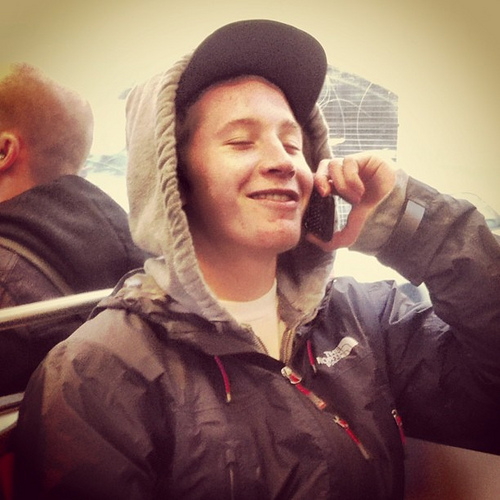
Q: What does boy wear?
A: Hooded jacket.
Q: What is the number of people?
A: Two.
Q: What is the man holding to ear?
A: Cellphone.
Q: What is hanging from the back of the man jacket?
A: Hood.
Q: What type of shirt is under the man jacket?
A: White t shirt.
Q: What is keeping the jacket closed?
A: Zipper.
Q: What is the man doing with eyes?
A: Closed.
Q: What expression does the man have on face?
A: Smiling.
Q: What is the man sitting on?
A: Bench.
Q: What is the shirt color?
A: White.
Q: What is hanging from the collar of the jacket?
A: String.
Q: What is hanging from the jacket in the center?
A: Zipper.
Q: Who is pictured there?
A: Young boy.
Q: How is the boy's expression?
A: Smiling.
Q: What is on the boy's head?
A: Cap.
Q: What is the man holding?
A: Cell phone.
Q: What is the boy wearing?
A: Hoodie.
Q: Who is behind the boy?
A: A man.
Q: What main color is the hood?
A: Gray.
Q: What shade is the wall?
A: Beige.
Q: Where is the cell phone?
A: In the front man's left hand.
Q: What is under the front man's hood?
A: Baseball cap.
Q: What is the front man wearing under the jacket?
A: White t-shirt.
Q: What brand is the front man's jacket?
A: The North Face.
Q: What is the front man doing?
A: Talking on the phone.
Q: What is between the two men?
A: Metal rail.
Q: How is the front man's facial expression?
A: Eyes closed, smiling.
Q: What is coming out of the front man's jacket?
A: Red strings.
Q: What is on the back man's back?
A: Black hood.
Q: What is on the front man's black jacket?
A: North Face letters and logo.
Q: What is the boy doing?
A: Talking on phone.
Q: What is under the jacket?
A: A shirt.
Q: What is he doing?
A: Talking on the phone.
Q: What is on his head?
A: A hat.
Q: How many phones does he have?
A: One.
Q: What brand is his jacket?
A: The North Face.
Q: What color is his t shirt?
A: White.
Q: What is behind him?
A: A man.